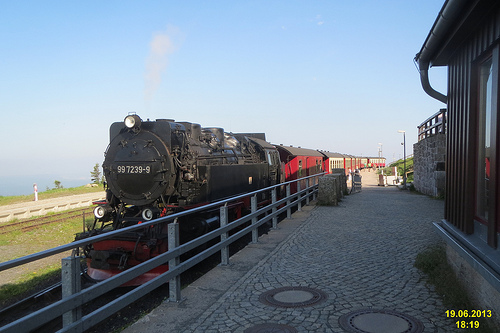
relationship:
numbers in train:
[110, 155, 166, 180] [80, 116, 330, 241]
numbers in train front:
[117, 165, 151, 174] [94, 114, 170, 220]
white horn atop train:
[122, 114, 140, 129] [82, 113, 390, 273]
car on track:
[82, 113, 388, 290] [0, 265, 180, 331]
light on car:
[123, 112, 145, 132] [82, 113, 388, 290]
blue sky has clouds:
[1, 2, 447, 195] [14, 108, 116, 158]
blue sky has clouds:
[1, 2, 447, 195] [274, 5, 329, 34]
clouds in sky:
[273, 80, 383, 149] [270, 19, 378, 74]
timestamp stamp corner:
[439, 303, 487, 323] [444, 300, 484, 320]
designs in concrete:
[258, 276, 327, 311] [244, 209, 456, 331]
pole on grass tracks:
[33, 178, 45, 204] [0, 197, 106, 237]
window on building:
[479, 62, 498, 154] [408, 0, 498, 325]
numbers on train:
[117, 165, 151, 174] [56, 133, 381, 296]